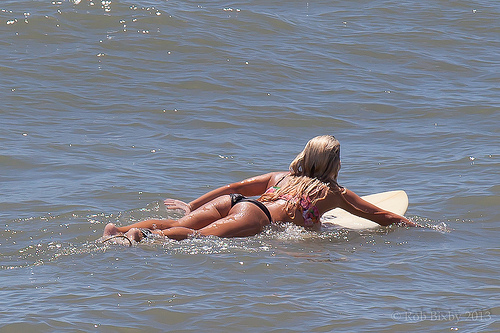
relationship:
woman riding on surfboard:
[99, 132, 426, 240] [320, 189, 410, 233]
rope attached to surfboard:
[94, 231, 137, 248] [320, 189, 410, 233]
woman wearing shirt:
[99, 132, 426, 240] [260, 177, 322, 229]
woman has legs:
[99, 132, 426, 240] [102, 192, 270, 241]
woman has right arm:
[99, 132, 426, 240] [335, 185, 423, 229]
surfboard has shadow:
[320, 189, 410, 233] [316, 215, 346, 232]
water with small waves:
[1, 0, 499, 332] [40, 74, 386, 134]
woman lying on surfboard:
[99, 132, 426, 240] [320, 189, 410, 233]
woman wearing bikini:
[99, 132, 426, 240] [226, 172, 322, 228]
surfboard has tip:
[320, 189, 410, 233] [385, 185, 411, 205]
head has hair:
[297, 131, 342, 183] [256, 131, 347, 221]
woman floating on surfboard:
[99, 132, 426, 240] [320, 189, 410, 233]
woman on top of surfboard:
[99, 132, 426, 240] [320, 189, 410, 233]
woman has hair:
[99, 132, 426, 240] [256, 131, 347, 221]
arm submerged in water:
[335, 185, 423, 229] [1, 0, 499, 332]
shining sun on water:
[2, 0, 237, 70] [1, 0, 499, 332]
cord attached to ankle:
[94, 231, 137, 248] [138, 226, 154, 242]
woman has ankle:
[99, 132, 426, 240] [138, 226, 154, 242]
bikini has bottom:
[226, 172, 322, 228] [223, 187, 274, 226]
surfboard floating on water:
[320, 189, 410, 233] [1, 0, 499, 332]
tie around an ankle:
[94, 231, 137, 248] [138, 226, 154, 242]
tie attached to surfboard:
[94, 231, 137, 248] [320, 189, 410, 233]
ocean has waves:
[1, 0, 499, 332] [2, 0, 498, 333]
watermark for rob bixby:
[388, 302, 493, 327] [400, 307, 463, 327]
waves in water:
[2, 0, 498, 333] [1, 0, 499, 332]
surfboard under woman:
[320, 189, 410, 233] [99, 132, 426, 240]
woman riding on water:
[99, 132, 426, 240] [1, 0, 499, 332]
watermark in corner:
[388, 302, 493, 327] [382, 286, 497, 332]